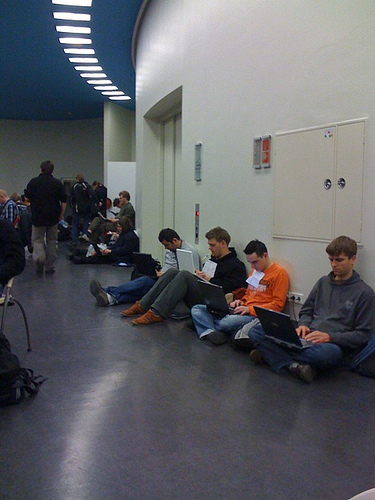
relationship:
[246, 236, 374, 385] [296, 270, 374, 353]
male wearing hoodie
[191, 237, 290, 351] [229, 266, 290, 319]
man wearing shirt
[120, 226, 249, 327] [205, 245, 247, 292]
man wearing hoodie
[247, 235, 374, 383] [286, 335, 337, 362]
male crosses leg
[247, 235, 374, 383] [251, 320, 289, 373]
male crosses leg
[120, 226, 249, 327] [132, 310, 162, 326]
man wears shoe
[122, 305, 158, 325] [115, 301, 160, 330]
shoes are on feet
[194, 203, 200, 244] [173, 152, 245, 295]
buttons are on wall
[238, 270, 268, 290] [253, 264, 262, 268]
paper under chin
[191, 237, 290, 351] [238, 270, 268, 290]
man has paper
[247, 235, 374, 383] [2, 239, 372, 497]
male sits on floor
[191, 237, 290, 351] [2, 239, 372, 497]
man sits on floor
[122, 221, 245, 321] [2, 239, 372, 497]
man sits on floor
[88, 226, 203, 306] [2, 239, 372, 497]
man sits on floor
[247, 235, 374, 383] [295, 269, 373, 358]
male has grey jacket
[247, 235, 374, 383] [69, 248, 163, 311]
male wears jeans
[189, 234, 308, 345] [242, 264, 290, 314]
man wears shirt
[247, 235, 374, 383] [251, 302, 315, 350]
male looks at laptop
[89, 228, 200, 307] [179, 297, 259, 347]
man wears jeans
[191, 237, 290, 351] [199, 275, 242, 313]
man looks at laptop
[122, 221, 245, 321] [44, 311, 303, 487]
man sits on floor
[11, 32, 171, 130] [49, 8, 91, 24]
ceiling has light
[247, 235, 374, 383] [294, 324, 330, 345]
male has hand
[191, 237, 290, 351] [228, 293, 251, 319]
man has hand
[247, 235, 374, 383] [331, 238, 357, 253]
male has hair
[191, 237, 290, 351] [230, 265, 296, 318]
man has shirt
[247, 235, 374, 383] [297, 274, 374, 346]
male has shirt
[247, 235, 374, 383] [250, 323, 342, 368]
male has jeans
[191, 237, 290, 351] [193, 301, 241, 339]
man has jeans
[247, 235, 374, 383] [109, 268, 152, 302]
male has jeans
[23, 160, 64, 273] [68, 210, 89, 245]
man has jeans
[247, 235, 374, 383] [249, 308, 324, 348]
male has laptop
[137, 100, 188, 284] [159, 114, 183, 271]
elevator has doors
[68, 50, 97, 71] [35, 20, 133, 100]
light in ceiling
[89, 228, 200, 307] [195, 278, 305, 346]
man have laptops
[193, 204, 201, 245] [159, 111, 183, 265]
buttons for doors